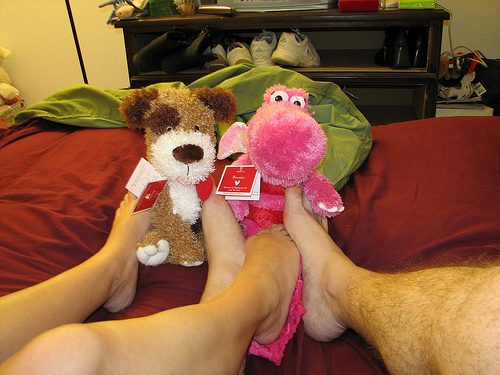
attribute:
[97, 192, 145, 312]
foot — white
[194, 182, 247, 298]
foot — white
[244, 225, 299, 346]
foot — white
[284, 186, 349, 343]
foot — white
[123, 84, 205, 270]
dog — spotted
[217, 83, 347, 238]
stuffed animal — pink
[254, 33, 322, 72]
shoes — white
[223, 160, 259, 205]
tag — red, square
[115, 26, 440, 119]
shelf — brown, wooden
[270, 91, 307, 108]
eyes — round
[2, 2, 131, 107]
wall — creme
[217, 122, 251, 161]
wing — pink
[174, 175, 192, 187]
tongue — pink